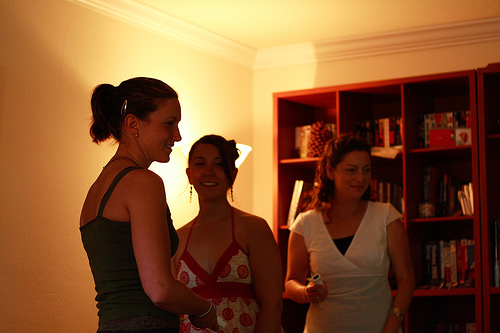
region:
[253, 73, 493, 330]
books on book shelf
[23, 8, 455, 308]
three young women gathered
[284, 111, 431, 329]
woman holding nintendo controller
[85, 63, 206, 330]
woman with barrett in her hair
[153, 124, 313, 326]
young woman with pink and white tank top on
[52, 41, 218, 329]
woman wearing green spaghetti strap tank top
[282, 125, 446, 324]
woman with gold bracelet or watch on left wrist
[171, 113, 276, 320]
woman wearing drop earrings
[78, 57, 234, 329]
woman wearing small earrings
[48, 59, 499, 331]
three women smiling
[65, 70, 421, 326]
Three young women standing together in a room.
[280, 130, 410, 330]
A young woman wearing a white shirt.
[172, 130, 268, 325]
A young woman wearing a polka dotted shirt.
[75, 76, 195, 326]
A young woman wearing a black tank top.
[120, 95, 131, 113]
The woman has a barrett in her hair.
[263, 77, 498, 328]
A wooden bookcase behind a woman.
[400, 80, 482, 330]
Books and nick nacks on the shelves.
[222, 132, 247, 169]
The edge of a white lamp behind a woman.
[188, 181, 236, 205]
The woman is wearing dangle earrings.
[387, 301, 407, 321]
The woman is wearing a bracelet on her arm.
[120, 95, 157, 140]
Silver clip in woman's hair.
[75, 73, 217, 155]
Woman's hair pulled back in pony tail.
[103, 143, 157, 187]
Woman wearing necklace around neck.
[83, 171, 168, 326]
Woman wearing green tank top.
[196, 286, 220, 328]
White band around woman's wrist.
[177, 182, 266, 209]
Woman wearing long earrings on ears.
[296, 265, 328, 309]
Woman holding wii remote.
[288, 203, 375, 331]
Woman wearing white shirt.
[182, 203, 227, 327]
Woman wearing white and red shirt.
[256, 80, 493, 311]
Large wood shelving unit near wall.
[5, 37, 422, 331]
woman standing in a lit room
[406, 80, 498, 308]
bookcase filled with books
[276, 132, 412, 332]
woman in white top holding a Wii controller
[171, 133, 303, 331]
young woman smiling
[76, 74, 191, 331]
young woman with a pony tail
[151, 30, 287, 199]
light lighting the wall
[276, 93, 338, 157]
big pine cone on a shelve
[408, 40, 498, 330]
brown shelving in front of the wall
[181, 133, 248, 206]
earrings on the girls ears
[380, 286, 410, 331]
silver bracelet on an arm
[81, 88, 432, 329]
Group of women standing together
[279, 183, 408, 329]
Woman wearing a white tshirt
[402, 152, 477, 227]
Books in a bookshelf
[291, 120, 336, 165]
Pine cone sitting on a shelf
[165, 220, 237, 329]
Woman wearing a spaghetti strap shirt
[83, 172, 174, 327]
Dark colored spaghetti strap shirt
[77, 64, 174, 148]
Woman has dark hair in a ponytail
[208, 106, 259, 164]
Lamp standing on the floor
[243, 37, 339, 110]
Light reflection on the wall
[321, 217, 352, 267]
Black shirt underneath her other shirt